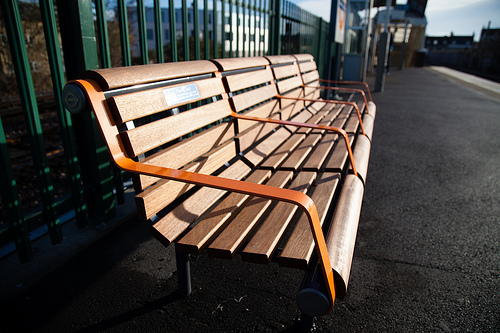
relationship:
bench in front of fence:
[71, 40, 385, 310] [81, 10, 266, 56]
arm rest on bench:
[144, 164, 289, 217] [55, 49, 417, 308]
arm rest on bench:
[156, 158, 290, 215] [55, 49, 417, 308]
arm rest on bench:
[192, 179, 305, 211] [71, 40, 385, 310]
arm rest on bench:
[242, 182, 322, 225] [71, 40, 385, 310]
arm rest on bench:
[202, 166, 272, 205] [55, 49, 417, 308]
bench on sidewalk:
[71, 40, 385, 310] [402, 133, 477, 318]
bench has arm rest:
[62, 54, 376, 333] [71, 80, 340, 314]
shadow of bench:
[23, 237, 183, 330] [71, 40, 385, 310]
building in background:
[119, 4, 276, 60] [4, 3, 495, 118]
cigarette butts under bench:
[207, 289, 251, 318] [71, 40, 385, 310]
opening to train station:
[372, 11, 411, 71] [316, 4, 431, 88]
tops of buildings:
[427, 21, 497, 39] [413, 17, 499, 80]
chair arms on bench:
[152, 80, 360, 298] [62, 45, 381, 330]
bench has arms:
[71, 40, 385, 310] [141, 79, 373, 299]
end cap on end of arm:
[296, 283, 334, 323] [62, 72, 344, 323]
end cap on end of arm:
[62, 83, 89, 118] [62, 72, 344, 323]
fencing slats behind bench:
[3, 0, 332, 263] [71, 40, 385, 310]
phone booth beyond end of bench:
[337, 3, 380, 97] [62, 54, 376, 333]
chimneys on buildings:
[439, 19, 493, 37] [413, 17, 499, 80]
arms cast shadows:
[103, 79, 371, 267] [140, 73, 324, 216]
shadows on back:
[140, 73, 324, 216] [68, 59, 320, 216]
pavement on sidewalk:
[6, 67, 499, 329] [333, 54, 499, 331]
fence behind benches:
[4, 0, 328, 276] [55, 49, 386, 299]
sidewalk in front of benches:
[351, 58, 484, 330] [57, 48, 386, 331]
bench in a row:
[62, 54, 376, 333] [188, 70, 370, 309]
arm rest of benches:
[69, 80, 332, 282] [87, 45, 421, 309]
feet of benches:
[165, 282, 323, 327] [63, 39, 413, 314]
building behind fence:
[117, 0, 303, 62] [19, 60, 62, 96]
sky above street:
[426, 1, 497, 39] [6, 59, 496, 326]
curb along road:
[426, 62, 497, 95] [4, 66, 495, 328]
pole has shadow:
[171, 242, 192, 292] [95, 287, 188, 317]